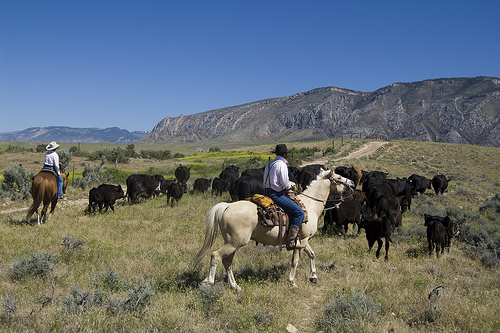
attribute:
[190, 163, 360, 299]
horse — palomino colored, white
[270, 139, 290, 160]
hat — black, white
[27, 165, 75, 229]
horse — brown, red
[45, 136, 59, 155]
hat — white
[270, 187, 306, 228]
jeans — blue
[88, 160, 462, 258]
cattle — black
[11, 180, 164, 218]
road — dirt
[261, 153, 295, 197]
shirt — white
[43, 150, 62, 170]
shirt — white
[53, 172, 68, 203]
jeans — blue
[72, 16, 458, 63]
sky — blue